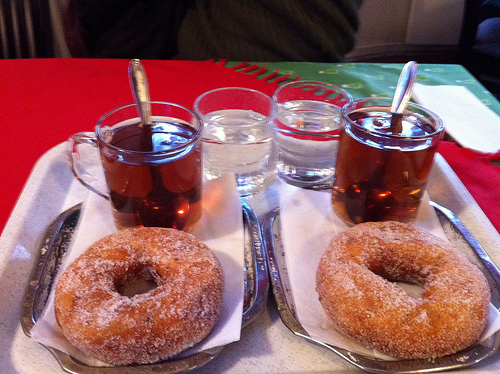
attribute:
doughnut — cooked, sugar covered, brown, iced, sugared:
[60, 224, 224, 372]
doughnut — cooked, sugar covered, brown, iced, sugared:
[313, 216, 495, 363]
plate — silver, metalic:
[21, 191, 275, 373]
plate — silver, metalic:
[263, 194, 499, 373]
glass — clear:
[56, 98, 209, 245]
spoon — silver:
[126, 54, 194, 236]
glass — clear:
[328, 94, 445, 233]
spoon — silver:
[342, 57, 418, 225]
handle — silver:
[127, 53, 168, 190]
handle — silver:
[374, 56, 419, 184]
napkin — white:
[404, 78, 500, 161]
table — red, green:
[2, 54, 500, 373]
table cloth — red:
[1, 56, 499, 365]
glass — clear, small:
[192, 89, 279, 212]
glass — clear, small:
[270, 76, 359, 196]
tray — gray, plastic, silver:
[0, 128, 496, 373]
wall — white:
[340, 0, 465, 57]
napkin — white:
[272, 175, 499, 363]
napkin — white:
[29, 173, 250, 358]